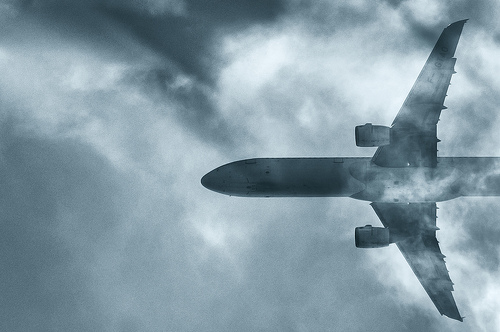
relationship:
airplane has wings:
[202, 8, 499, 325] [377, 20, 468, 323]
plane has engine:
[202, 8, 499, 325] [354, 124, 402, 248]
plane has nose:
[202, 8, 499, 325] [203, 152, 361, 218]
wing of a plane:
[377, 20, 468, 323] [202, 8, 499, 325]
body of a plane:
[201, 157, 499, 206] [202, 8, 499, 325]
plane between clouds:
[202, 8, 499, 325] [9, 13, 342, 136]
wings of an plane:
[377, 20, 468, 323] [202, 8, 499, 325]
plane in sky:
[202, 8, 499, 325] [5, 3, 499, 330]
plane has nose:
[202, 8, 499, 325] [201, 13, 499, 321]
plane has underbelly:
[202, 8, 499, 325] [270, 164, 421, 194]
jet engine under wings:
[360, 155, 451, 195] [377, 20, 468, 323]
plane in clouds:
[202, 8, 499, 325] [3, 3, 493, 329]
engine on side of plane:
[354, 124, 402, 248] [202, 8, 499, 325]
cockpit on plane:
[203, 155, 272, 197] [202, 8, 499, 325]